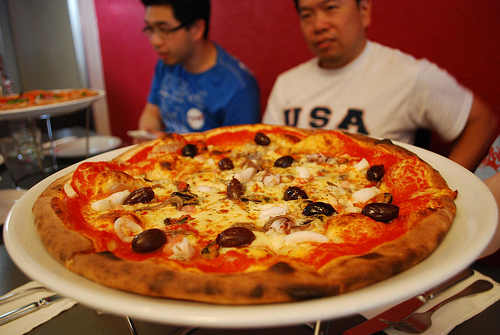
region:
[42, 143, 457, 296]
The crust is golden brown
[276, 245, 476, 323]
The plate is white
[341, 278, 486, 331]
The silver ware is under the plate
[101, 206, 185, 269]
The pizza has olives on it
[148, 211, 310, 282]
The cheese is melted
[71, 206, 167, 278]
The pizza has tomato sauce on it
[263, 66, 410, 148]
The man's shirt says USA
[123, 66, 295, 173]
The man has a blue shirt on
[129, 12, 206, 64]
The man has glasses on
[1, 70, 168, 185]
The pizza is in the background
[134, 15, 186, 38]
The black eyeglasses the man is wearing.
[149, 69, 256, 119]
The blue shirt the man is wearing.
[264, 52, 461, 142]
The white t-shirt the man is wearing.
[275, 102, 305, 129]
The letter U on the man's shirt.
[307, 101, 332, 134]
The letter S on the man's shirt.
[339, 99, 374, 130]
The letter A on the man's shirt.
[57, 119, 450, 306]
The pizza on a plate in front of the man with the white shirt.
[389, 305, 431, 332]
The sporks on the fork to the right of the man in the white t-shirt.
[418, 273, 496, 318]
The handle of the fork.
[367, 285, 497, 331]
The white napkin the fork is placed on.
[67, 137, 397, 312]
a pizza on a pate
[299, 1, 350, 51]
a face of a person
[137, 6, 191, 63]
a face with glasses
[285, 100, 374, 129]
the letters "USA" on a shirt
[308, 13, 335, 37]
a nose of a person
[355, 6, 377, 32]
an ear of a person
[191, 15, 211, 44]
an ear of a person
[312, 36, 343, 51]
a mouth of a person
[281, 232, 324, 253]
melted cheese on a pizza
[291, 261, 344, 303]
the crust of a pizza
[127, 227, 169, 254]
one whole black olive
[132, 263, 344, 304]
crust of a pizza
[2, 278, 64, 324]
silverware on a napkin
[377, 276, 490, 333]
fork on a napkin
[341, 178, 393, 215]
small piece of garlic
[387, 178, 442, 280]
tomato sauce on pizza crust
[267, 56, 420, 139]
shirt that syas u.s.a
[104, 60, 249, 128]
blue and white shirt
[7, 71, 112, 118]
pizza on a white plate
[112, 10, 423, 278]
two people next to a pizza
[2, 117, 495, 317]
round pizza on a plate.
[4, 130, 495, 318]
The plate is white.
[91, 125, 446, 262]
Olives on a pizza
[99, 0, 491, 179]
Two men behind the pizza.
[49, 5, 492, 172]
The wall behind the men is red.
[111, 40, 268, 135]
Man on the left is wearing blue.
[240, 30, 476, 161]
Man on the right wearing white.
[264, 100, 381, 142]
USA written on the right man's shirt.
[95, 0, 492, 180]
The two men are Asian.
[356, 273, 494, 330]
Silverware on the table.